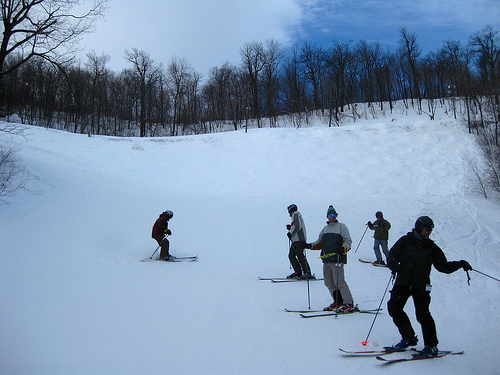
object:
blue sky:
[0, 0, 500, 113]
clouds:
[3, 1, 500, 118]